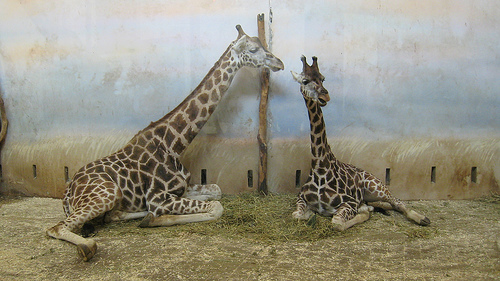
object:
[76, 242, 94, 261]
hoof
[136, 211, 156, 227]
hoof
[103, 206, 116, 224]
hoof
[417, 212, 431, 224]
hoof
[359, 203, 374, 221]
hoof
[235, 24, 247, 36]
horns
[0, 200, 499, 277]
field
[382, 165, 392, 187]
post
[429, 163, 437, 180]
post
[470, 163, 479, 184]
post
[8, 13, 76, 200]
painting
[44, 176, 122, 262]
legs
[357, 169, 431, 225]
legs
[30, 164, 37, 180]
hole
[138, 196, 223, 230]
leg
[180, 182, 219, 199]
leg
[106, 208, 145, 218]
leg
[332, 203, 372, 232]
legs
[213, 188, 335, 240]
hay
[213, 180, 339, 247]
pile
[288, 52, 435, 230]
griaffe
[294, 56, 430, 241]
giraffe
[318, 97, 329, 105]
mouth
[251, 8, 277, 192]
pole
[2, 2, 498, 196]
wall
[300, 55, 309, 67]
horns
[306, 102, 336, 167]
long neck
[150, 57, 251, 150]
long neck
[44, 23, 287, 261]
giraffe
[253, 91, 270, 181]
wood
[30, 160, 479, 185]
lines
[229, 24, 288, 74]
head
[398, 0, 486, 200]
painted wall